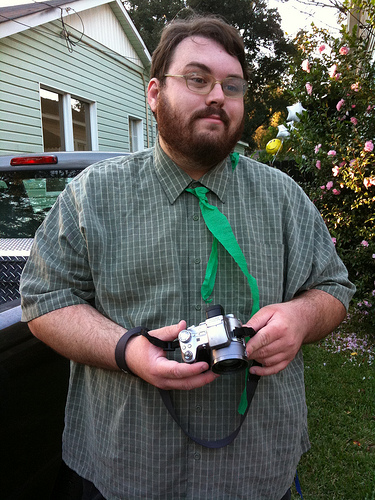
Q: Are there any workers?
A: No, there are no workers.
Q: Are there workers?
A: No, there are no workers.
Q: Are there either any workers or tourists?
A: No, there are no workers or tourists.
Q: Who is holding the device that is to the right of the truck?
A: The man is holding the camera.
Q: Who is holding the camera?
A: The man is holding the camera.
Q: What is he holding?
A: The man is holding the camera.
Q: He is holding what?
A: The man is holding the camera.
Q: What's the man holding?
A: The man is holding the camera.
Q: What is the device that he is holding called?
A: The device is a camera.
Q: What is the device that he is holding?
A: The device is a camera.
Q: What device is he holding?
A: The man is holding the camera.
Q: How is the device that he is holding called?
A: The device is a camera.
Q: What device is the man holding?
A: The man is holding the camera.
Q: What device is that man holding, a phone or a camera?
A: The man is holding a camera.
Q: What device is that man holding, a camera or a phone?
A: The man is holding a camera.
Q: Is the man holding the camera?
A: Yes, the man is holding the camera.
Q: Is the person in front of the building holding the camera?
A: Yes, the man is holding the camera.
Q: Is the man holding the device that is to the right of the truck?
A: Yes, the man is holding the camera.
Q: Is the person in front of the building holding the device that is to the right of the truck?
A: Yes, the man is holding the camera.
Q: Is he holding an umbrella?
A: No, the man is holding the camera.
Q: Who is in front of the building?
A: The man is in front of the building.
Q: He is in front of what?
A: The man is in front of the building.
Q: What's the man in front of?
A: The man is in front of the building.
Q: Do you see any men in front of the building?
A: Yes, there is a man in front of the building.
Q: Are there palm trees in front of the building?
A: No, there is a man in front of the building.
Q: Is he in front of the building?
A: Yes, the man is in front of the building.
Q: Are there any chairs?
A: No, there are no chairs.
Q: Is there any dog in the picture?
A: No, there are no dogs.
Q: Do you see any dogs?
A: No, there are no dogs.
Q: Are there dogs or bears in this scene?
A: No, there are no dogs or bears.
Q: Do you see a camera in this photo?
A: Yes, there is a camera.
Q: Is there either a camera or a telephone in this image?
A: Yes, there is a camera.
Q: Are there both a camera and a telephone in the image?
A: No, there is a camera but no phones.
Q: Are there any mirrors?
A: No, there are no mirrors.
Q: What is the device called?
A: The device is a camera.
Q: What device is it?
A: The device is a camera.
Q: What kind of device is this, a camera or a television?
A: This is a camera.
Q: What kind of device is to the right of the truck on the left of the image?
A: The device is a camera.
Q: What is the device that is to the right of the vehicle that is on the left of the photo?
A: The device is a camera.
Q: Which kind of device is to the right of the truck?
A: The device is a camera.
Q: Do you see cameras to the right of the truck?
A: Yes, there is a camera to the right of the truck.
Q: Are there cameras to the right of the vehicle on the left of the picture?
A: Yes, there is a camera to the right of the truck.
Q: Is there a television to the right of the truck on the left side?
A: No, there is a camera to the right of the truck.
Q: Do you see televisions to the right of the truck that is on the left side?
A: No, there is a camera to the right of the truck.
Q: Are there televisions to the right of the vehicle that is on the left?
A: No, there is a camera to the right of the truck.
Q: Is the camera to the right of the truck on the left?
A: Yes, the camera is to the right of the truck.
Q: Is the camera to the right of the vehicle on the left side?
A: Yes, the camera is to the right of the truck.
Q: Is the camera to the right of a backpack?
A: No, the camera is to the right of the truck.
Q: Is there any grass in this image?
A: Yes, there is grass.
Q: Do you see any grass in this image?
A: Yes, there is grass.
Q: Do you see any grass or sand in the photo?
A: Yes, there is grass.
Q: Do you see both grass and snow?
A: No, there is grass but no snow.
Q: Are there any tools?
A: No, there are no tools.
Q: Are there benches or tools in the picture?
A: No, there are no tools or benches.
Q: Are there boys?
A: No, there are no boys.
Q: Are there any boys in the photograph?
A: No, there are no boys.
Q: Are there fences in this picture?
A: No, there are no fences.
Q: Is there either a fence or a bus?
A: No, there are no fences or buses.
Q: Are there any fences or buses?
A: No, there are no fences or buses.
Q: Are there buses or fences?
A: No, there are no fences or buses.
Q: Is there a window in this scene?
A: Yes, there is a window.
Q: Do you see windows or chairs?
A: Yes, there is a window.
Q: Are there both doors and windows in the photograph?
A: No, there is a window but no doors.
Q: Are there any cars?
A: No, there are no cars.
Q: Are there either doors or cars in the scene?
A: No, there are no cars or doors.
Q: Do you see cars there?
A: No, there are no cars.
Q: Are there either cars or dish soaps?
A: No, there are no cars or dish soaps.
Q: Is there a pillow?
A: No, there are no pillows.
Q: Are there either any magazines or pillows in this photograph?
A: No, there are no pillows or magazines.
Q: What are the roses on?
A: The roses are on the bush.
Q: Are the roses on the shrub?
A: Yes, the roses are on the shrub.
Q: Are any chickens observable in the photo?
A: No, there are no chickens.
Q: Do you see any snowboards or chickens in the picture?
A: No, there are no chickens or snowboards.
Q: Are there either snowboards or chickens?
A: No, there are no chickens or snowboards.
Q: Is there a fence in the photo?
A: No, there are no fences.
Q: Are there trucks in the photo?
A: Yes, there is a truck.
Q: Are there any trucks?
A: Yes, there is a truck.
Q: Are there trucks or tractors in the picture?
A: Yes, there is a truck.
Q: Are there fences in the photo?
A: No, there are no fences.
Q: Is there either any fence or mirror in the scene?
A: No, there are no fences or mirrors.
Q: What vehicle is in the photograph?
A: The vehicle is a truck.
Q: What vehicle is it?
A: The vehicle is a truck.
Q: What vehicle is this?
A: This is a truck.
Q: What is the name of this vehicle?
A: This is a truck.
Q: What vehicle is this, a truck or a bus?
A: This is a truck.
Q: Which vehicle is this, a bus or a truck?
A: This is a truck.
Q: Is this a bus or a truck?
A: This is a truck.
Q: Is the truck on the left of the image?
A: Yes, the truck is on the left of the image.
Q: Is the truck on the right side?
A: No, the truck is on the left of the image.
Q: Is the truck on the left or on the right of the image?
A: The truck is on the left of the image.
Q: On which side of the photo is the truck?
A: The truck is on the left of the image.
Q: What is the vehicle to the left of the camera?
A: The vehicle is a truck.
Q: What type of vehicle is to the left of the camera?
A: The vehicle is a truck.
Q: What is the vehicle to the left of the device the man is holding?
A: The vehicle is a truck.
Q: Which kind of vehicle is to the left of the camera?
A: The vehicle is a truck.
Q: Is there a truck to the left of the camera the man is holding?
A: Yes, there is a truck to the left of the camera.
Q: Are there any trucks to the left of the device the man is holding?
A: Yes, there is a truck to the left of the camera.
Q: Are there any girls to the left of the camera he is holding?
A: No, there is a truck to the left of the camera.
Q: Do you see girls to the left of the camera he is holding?
A: No, there is a truck to the left of the camera.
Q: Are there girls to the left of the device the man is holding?
A: No, there is a truck to the left of the camera.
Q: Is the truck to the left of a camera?
A: Yes, the truck is to the left of a camera.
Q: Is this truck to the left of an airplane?
A: No, the truck is to the left of a camera.